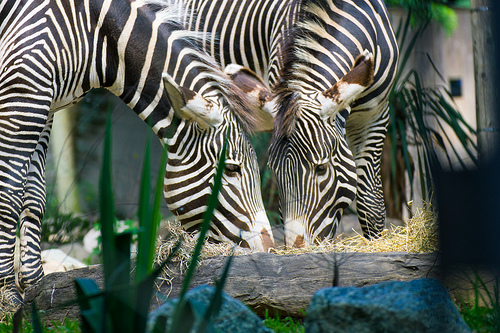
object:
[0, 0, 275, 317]
zebra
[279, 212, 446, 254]
hay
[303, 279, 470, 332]
rock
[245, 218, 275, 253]
nose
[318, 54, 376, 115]
ear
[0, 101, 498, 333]
grass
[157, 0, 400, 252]
zebra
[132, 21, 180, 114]
stripe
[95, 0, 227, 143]
neck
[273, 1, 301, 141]
mane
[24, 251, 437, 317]
rock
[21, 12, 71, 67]
fur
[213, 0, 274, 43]
fur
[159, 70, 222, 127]
ear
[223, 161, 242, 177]
eye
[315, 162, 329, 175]
eye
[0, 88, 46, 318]
leg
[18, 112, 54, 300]
leg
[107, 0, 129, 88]
stripe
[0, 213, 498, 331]
ground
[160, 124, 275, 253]
head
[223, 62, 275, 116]
ear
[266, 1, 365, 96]
neck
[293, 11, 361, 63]
stripe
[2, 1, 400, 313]
couple